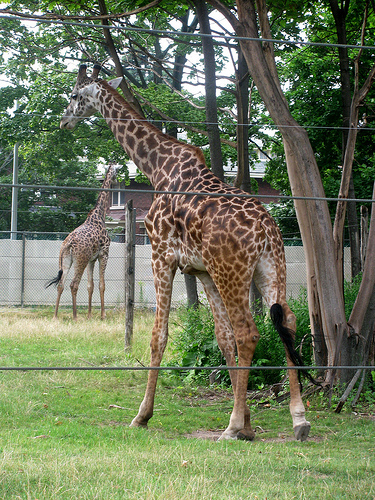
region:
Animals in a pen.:
[38, 60, 319, 448]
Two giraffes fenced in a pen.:
[35, 58, 313, 452]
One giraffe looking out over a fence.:
[40, 163, 123, 324]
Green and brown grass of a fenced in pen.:
[1, 336, 372, 496]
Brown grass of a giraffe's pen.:
[3, 308, 150, 339]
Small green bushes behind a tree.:
[169, 298, 309, 384]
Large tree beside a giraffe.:
[238, 64, 373, 385]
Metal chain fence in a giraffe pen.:
[3, 228, 146, 308]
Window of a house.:
[110, 183, 128, 208]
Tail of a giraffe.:
[40, 235, 75, 291]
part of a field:
[336, 442, 344, 458]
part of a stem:
[320, 349, 330, 369]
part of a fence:
[22, 276, 32, 289]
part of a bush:
[203, 324, 212, 333]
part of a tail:
[275, 322, 289, 340]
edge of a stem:
[317, 285, 334, 313]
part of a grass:
[153, 444, 162, 456]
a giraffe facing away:
[55, 57, 313, 447]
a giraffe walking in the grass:
[61, 60, 314, 440]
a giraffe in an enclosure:
[47, 58, 313, 441]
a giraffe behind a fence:
[62, 60, 311, 444]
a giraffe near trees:
[58, 57, 314, 441]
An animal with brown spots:
[58, 59, 324, 442]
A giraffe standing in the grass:
[52, 57, 331, 447]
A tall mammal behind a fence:
[59, 54, 327, 434]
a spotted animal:
[63, 54, 325, 444]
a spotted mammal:
[53, 58, 330, 445]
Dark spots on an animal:
[217, 219, 245, 253]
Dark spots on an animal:
[221, 271, 236, 296]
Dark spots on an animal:
[259, 255, 281, 287]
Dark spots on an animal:
[143, 261, 180, 296]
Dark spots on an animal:
[150, 288, 175, 320]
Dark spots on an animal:
[144, 317, 174, 348]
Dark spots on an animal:
[140, 342, 171, 383]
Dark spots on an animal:
[131, 380, 170, 418]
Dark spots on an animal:
[144, 205, 180, 240]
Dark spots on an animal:
[196, 196, 238, 225]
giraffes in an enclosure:
[27, 62, 353, 453]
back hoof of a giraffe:
[291, 415, 315, 450]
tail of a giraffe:
[256, 212, 326, 407]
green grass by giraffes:
[6, 339, 124, 499]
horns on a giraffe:
[75, 56, 103, 86]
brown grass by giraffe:
[11, 316, 103, 335]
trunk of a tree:
[267, 87, 372, 403]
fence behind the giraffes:
[5, 230, 49, 305]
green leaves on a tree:
[284, 21, 345, 159]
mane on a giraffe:
[112, 88, 203, 173]